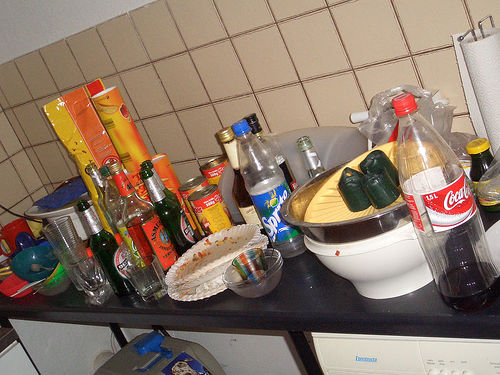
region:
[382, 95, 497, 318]
1.5 Liter plastic bottle of Coca Cola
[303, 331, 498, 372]
Front control panel of a dish washer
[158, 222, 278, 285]
Used stack of paper plates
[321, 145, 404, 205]
Three burned green candles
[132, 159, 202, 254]
Two open green bottles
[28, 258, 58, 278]
Spoon in a blue bowl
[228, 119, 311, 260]
Open plastic bottle of Sprite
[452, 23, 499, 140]
Paper towel holder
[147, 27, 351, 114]
Cream colored tile back splash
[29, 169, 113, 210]
Blue napkin on a white plate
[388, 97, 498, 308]
Coca-Cola bottle on the counter.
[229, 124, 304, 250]
Sprite bottle on the counter.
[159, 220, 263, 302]
Stack of dirty paper plates.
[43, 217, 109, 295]
Shot glasses in a stack.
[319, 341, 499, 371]
Top of the dishwasher.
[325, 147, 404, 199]
Candles in a bowl.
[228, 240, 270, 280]
Shot glass in a bowl.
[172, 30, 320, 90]
Tiles on the wall.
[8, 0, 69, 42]
White paint on the wall.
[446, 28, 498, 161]
Roll of paper towels.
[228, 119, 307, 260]
The Sprite bottle on the counter.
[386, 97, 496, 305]
The Coca-Cola bottle on the counter.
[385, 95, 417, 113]
The red lid of the Coca-Cola bottle.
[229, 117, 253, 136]
The blue lid of the Sprite bottle.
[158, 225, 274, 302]
The dirty paper plates on the counter.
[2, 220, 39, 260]
The red mug on the left side of the counter.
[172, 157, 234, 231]
The three yellow and red cans on the counter.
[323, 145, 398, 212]
The three green burnt out candles inside of the white bowl.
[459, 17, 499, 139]
The roll of paper towels on the right side of the counter.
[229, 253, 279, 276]
The multicolored cup inside of the clear bowl next to the paper plates.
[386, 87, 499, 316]
a plastic bottle for coca cola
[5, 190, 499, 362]
a counter filled with assorted bottles and plates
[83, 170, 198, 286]
many empty beer bottles on the counter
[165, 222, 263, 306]
a stack of paper plates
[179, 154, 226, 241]
some cans sitting on the counter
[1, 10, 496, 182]
the wall next to the counter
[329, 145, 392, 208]
some green candles sitting in a bowl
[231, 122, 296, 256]
an empty bottle of sprite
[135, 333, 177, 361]
a blue scoop on the box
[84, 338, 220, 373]
a kitty litter box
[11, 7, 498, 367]
a crowded counter in a kitchen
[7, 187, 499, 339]
the kitchen counter is black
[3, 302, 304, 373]
the cabinets in the kitchen are white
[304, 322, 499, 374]
a dishwasher is installed under the counter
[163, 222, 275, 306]
soiled paper plates are on the counter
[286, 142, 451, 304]
bowls are piled up with green candles on top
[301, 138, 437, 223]
the candles are sitting on a yellow tupperware lid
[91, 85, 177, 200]
a canister of potato chips is on a box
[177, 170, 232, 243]
canned goods are on the counter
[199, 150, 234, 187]
an empty can is on the counter